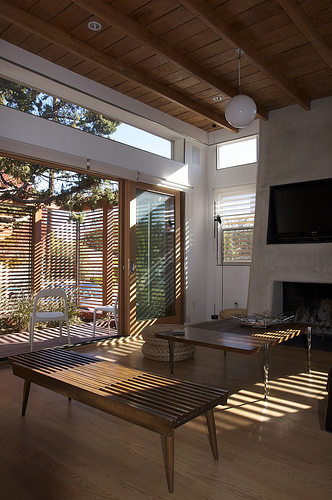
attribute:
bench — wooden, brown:
[18, 349, 218, 456]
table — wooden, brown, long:
[153, 315, 322, 377]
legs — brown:
[170, 345, 291, 385]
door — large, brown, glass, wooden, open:
[121, 189, 189, 325]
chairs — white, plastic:
[27, 287, 122, 353]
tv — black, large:
[259, 174, 331, 254]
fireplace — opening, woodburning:
[270, 266, 330, 319]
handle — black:
[126, 255, 138, 274]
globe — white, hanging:
[228, 98, 254, 127]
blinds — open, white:
[227, 193, 263, 249]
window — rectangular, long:
[7, 85, 207, 166]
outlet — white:
[224, 298, 241, 311]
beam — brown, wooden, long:
[41, 32, 267, 90]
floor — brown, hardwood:
[60, 350, 319, 481]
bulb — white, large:
[230, 101, 244, 127]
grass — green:
[13, 302, 92, 325]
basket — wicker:
[209, 301, 258, 323]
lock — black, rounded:
[123, 261, 141, 287]